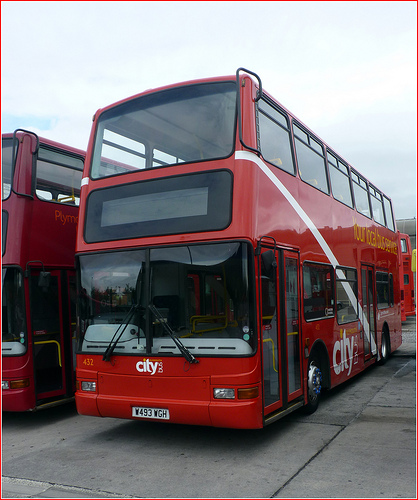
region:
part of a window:
[148, 128, 181, 162]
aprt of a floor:
[332, 433, 351, 468]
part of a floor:
[314, 433, 328, 464]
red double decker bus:
[70, 64, 403, 430]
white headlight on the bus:
[210, 385, 237, 401]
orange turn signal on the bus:
[235, 385, 260, 400]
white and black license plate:
[130, 403, 171, 420]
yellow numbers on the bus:
[79, 355, 95, 367]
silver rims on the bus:
[305, 357, 324, 405]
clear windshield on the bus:
[73, 239, 258, 357]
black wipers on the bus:
[99, 302, 199, 367]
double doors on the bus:
[254, 239, 306, 419]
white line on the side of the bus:
[232, 147, 380, 356]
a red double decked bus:
[71, 64, 402, 430]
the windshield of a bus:
[69, 232, 252, 358]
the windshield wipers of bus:
[147, 301, 192, 361]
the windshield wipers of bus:
[97, 295, 136, 358]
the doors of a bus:
[255, 237, 304, 415]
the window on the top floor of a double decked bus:
[89, 70, 245, 173]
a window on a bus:
[255, 91, 295, 175]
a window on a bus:
[289, 112, 332, 201]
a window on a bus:
[333, 262, 360, 327]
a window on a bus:
[35, 139, 83, 208]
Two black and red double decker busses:
[1, 62, 414, 440]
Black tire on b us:
[293, 351, 333, 423]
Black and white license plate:
[127, 403, 177, 422]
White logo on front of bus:
[133, 350, 164, 378]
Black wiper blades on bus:
[103, 292, 203, 370]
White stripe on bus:
[230, 148, 390, 364]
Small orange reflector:
[239, 385, 256, 399]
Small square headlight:
[212, 386, 232, 400]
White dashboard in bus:
[85, 325, 256, 359]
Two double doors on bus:
[252, 241, 311, 421]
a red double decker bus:
[70, 66, 400, 429]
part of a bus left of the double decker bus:
[0, 125, 131, 420]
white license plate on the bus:
[127, 403, 164, 413]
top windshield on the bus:
[86, 77, 229, 173]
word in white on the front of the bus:
[134, 356, 152, 368]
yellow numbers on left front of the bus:
[79, 354, 91, 363]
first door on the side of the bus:
[255, 235, 298, 412]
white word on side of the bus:
[329, 327, 350, 372]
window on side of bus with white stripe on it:
[333, 263, 354, 320]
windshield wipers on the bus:
[100, 265, 197, 362]